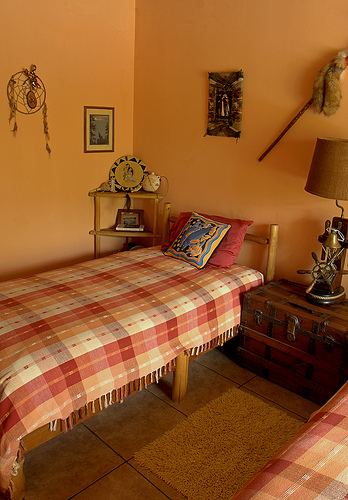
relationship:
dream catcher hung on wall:
[6, 64, 51, 155] [132, 1, 346, 294]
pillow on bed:
[160, 208, 252, 269] [2, 215, 272, 432]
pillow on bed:
[164, 210, 229, 267] [2, 215, 272, 432]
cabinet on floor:
[239, 286, 348, 406] [19, 351, 320, 498]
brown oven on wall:
[82, 101, 116, 156] [1, 0, 135, 282]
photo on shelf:
[95, 197, 160, 237] [89, 223, 165, 236]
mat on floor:
[136, 385, 306, 498] [19, 351, 320, 498]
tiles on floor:
[43, 438, 119, 498] [29, 432, 221, 497]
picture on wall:
[203, 69, 242, 145] [132, 1, 346, 294]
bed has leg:
[0, 206, 281, 490] [174, 348, 191, 396]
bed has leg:
[0, 206, 281, 490] [169, 352, 194, 407]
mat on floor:
[136, 385, 306, 498] [0, 333, 347, 498]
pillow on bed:
[160, 208, 252, 269] [0, 206, 281, 490]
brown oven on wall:
[82, 101, 116, 156] [110, 32, 184, 114]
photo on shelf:
[114, 208, 142, 225] [87, 223, 162, 237]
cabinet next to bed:
[89, 182, 171, 258] [0, 206, 281, 490]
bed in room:
[0, 206, 281, 496] [1, 1, 346, 498]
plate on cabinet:
[105, 155, 146, 192] [245, 286, 342, 387]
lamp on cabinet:
[297, 138, 347, 305] [239, 286, 348, 406]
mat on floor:
[136, 385, 306, 498] [52, 405, 286, 490]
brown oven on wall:
[82, 101, 116, 156] [7, 37, 144, 232]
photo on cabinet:
[114, 208, 142, 225] [89, 182, 171, 258]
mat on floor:
[136, 385, 306, 498] [154, 399, 265, 483]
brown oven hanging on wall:
[82, 101, 116, 156] [29, 55, 122, 227]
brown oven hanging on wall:
[82, 101, 116, 156] [12, 43, 127, 253]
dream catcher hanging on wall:
[6, 64, 51, 155] [1, 0, 135, 282]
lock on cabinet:
[283, 314, 305, 346] [239, 286, 348, 406]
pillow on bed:
[164, 210, 229, 267] [1, 196, 278, 449]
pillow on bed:
[162, 208, 252, 268] [1, 196, 278, 449]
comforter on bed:
[54, 295, 173, 364] [1, 243, 229, 380]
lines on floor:
[70, 418, 163, 498] [19, 351, 320, 498]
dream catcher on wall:
[6, 64, 51, 155] [5, 158, 87, 228]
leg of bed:
[173, 351, 187, 399] [0, 206, 281, 490]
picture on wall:
[217, 63, 252, 143] [152, 8, 300, 207]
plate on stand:
[108, 155, 146, 192] [85, 184, 169, 252]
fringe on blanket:
[42, 316, 258, 432] [0, 235, 277, 484]